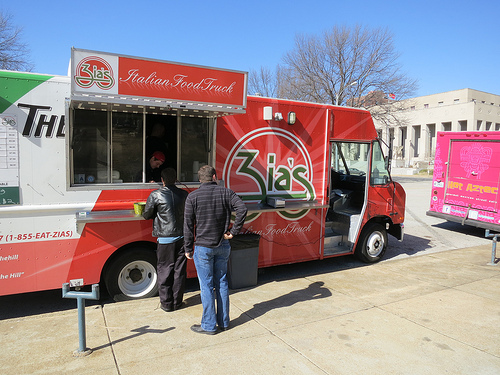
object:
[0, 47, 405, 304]
truck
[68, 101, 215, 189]
window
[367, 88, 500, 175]
building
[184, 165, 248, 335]
person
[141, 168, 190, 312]
person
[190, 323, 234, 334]
shoes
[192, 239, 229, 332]
pants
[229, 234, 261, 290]
bag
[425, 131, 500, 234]
truck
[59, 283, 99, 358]
pole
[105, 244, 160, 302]
tire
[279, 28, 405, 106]
tree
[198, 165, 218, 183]
hair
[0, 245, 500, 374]
sidewalk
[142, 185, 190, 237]
jack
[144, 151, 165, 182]
man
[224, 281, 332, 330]
shadow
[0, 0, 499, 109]
sky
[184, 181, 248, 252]
shirt